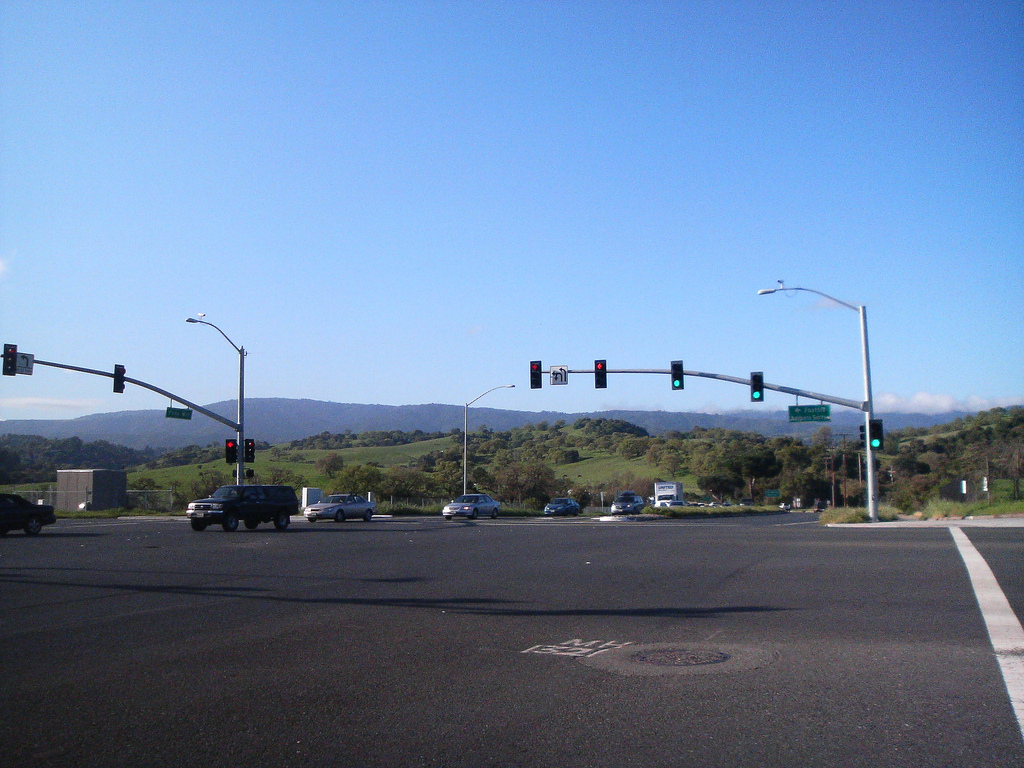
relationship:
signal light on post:
[661, 360, 687, 389] [531, 352, 881, 515]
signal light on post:
[734, 359, 776, 409] [784, 357, 921, 526]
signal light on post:
[857, 404, 894, 463] [838, 309, 916, 565]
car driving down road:
[186, 484, 301, 532] [125, 510, 625, 698]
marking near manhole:
[548, 616, 799, 722] [466, 536, 868, 765]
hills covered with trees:
[261, 391, 733, 582] [438, 441, 583, 521]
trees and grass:
[438, 441, 583, 521] [570, 446, 698, 524]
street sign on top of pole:
[762, 396, 829, 435] [751, 264, 922, 571]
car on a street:
[177, 474, 283, 546] [43, 476, 888, 760]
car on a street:
[414, 482, 516, 541] [356, 499, 665, 638]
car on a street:
[13, 487, 68, 542] [21, 504, 425, 764]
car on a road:
[525, 480, 588, 532] [0, 514, 1024, 768]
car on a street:
[605, 493, 632, 519] [533, 493, 883, 681]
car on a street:
[778, 502, 791, 511] [676, 474, 990, 680]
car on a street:
[689, 482, 776, 526] [639, 510, 985, 642]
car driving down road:
[186, 484, 301, 532] [147, 471, 582, 666]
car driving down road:
[281, 465, 435, 548] [214, 493, 716, 682]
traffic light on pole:
[3, 345, 40, 380] [0, 345, 256, 512]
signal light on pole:
[750, 371, 764, 402] [517, 341, 887, 426]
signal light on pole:
[673, 360, 686, 390] [517, 341, 887, 426]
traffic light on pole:
[577, 347, 616, 387] [517, 341, 887, 426]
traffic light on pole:
[523, 347, 549, 393] [517, 341, 887, 426]